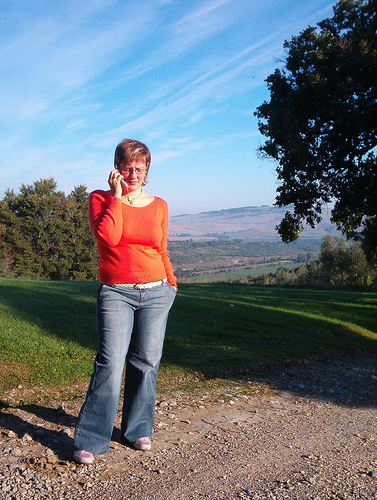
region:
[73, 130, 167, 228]
A lady on the cellphone.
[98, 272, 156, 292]
The woman is wearing a white belt.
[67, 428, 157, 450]
The sneakers are pink.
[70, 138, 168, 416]
The lady is standing in the rocks.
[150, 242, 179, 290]
Hand in the jeans pocket.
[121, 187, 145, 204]
The lady is wearing a necklace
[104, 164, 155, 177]
The woman is wearing glasses.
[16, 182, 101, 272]
A tree behind the lady.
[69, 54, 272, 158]
The sky is clear and blue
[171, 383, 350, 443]
Rocks on the ground.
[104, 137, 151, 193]
The woman's hair is brown.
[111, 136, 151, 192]
The woman's hair is short.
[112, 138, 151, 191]
The woman is wearing glasses.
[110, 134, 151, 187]
The woman is holding a cell phone.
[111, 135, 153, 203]
The woman is wearing a necklace.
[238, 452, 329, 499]
The ground is gravel.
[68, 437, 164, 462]
The woman's shoes are pink and white.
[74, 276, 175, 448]
The woman is wearing blue jeans.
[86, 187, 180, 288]
The woman is wearing a orange shirt.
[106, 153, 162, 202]
the head of a woman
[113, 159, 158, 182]
the eyes of a woman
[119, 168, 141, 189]
the nose of a woman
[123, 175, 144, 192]
the mouth of a woman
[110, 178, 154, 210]
the chin of a woman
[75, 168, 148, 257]
the arm of a woman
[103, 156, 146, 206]
the hand of a woman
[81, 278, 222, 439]
the leg of a woman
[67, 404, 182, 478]
the feet of a woman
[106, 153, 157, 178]
the hair of a woman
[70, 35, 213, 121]
Sky is blue color.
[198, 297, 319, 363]
Grass is green color.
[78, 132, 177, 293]
Woman is wearing orange shirt.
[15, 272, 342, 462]
Shadow falls on ground.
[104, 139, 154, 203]
Woman is talking in cell phone.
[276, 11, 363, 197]
Leaves are green color.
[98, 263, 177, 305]
Woman is wearing white belt.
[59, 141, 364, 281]
Small foot hills behind the woman.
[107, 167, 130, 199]
Cell phone is grey color.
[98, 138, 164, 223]
Woman is wearing chain in neck.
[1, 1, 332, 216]
thin clouds in sky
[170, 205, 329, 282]
valley in background horizon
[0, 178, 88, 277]
green leaves on tree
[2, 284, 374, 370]
shadow on green grass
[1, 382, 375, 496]
stones on dirt road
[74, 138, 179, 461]
standing woman on cell phone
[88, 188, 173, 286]
long sleeve red sweater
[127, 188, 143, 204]
jewelry on woman's neck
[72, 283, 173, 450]
blue jeans on legs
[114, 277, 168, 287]
white belt on pants